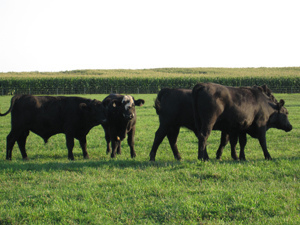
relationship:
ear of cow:
[279, 99, 284, 106] [188, 79, 288, 158]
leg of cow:
[260, 134, 276, 162] [188, 79, 288, 158]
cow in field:
[145, 75, 293, 162] [78, 142, 236, 181]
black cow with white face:
[100, 93, 144, 158] [120, 95, 135, 118]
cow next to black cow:
[1, 92, 112, 160] [100, 93, 145, 158]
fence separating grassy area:
[0, 82, 299, 93] [0, 95, 299, 223]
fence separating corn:
[0, 82, 299, 93] [0, 63, 298, 83]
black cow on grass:
[100, 93, 145, 158] [8, 158, 299, 224]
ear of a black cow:
[138, 87, 150, 130] [149, 85, 278, 161]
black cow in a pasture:
[100, 93, 145, 158] [20, 62, 274, 187]